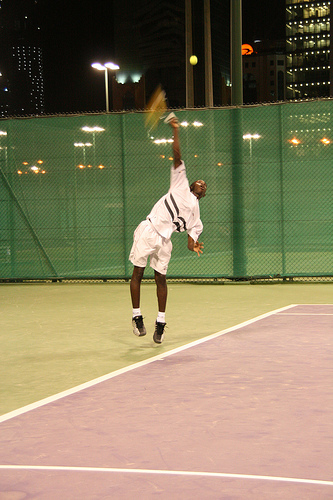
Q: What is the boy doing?
A: Playing tennins.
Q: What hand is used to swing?
A: Right.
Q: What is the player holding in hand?
A: Racket.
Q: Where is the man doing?
A: Swinging racket.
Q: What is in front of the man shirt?
A: Two stripes.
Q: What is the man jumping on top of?
A: Court.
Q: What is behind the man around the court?
A: Fence.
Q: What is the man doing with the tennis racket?
A: Swinging.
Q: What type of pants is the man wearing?
A: Shorts.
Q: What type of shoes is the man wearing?
A: Sneakers.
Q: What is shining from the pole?
A: Light.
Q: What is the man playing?
A: Tennis.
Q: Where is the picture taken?
A: Tennis court.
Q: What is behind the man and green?
A: A fence.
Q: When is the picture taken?
A: Evening.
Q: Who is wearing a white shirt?
A: The player.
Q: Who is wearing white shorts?
A: A man.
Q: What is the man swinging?
A: Tennis racket.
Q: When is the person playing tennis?
A: At night.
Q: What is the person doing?
A: Hitting a tennis ball.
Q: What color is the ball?
A: Yellow.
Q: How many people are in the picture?
A: One.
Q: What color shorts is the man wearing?
A: White.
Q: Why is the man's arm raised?
A: To hit a ball.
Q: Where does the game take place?
A: On a tennis court.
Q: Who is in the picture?
A: A tennis player.